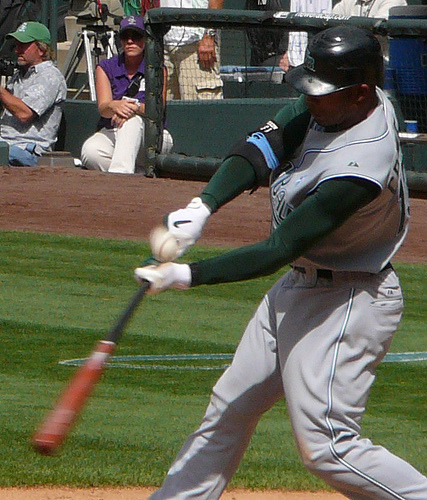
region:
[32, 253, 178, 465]
the baseball bat has two colors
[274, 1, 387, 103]
the player`s helmet is black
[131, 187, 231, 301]
player is wearing gloves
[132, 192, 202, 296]
the gloves are white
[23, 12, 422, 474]
the man is swinging the bat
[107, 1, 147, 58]
the woman is wearing sunglasses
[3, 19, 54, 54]
the hat is green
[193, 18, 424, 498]
the uniform is grey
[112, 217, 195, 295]
the ball is moving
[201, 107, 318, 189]
the player is wearing an arm brace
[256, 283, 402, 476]
The pair of pants is grey.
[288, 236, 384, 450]
The pair of pants is grey.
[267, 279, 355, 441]
The pair of pants is grey.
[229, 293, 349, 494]
The pair of pants is grey.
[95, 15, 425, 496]
The batter is left-handed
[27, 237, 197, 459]
The bat is black and red.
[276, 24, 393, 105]
The batter's helmet is black.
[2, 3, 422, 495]
The batter is swinging a bat.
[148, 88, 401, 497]
The batter's uniform is grey.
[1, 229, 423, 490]
The grass is green.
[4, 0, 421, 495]
The sport is baseball.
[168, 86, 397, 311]
Player's under shirt is green.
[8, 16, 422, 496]
Photo taken during the day.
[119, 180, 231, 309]
White batting gloves on the player.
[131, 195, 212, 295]
pair of white batting gloves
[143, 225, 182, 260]
baseball in flight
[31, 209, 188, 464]
a bat in mid-swing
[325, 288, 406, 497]
stripe on player's left leg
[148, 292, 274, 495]
player swinging against stiff front leg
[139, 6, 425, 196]
padded railing near baseball field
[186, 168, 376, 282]
left arm of batter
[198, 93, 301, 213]
right arm of batter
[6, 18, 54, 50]
green ball cap with white writing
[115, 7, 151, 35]
a purple ball cap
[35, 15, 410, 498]
a baseball player in the midst of swinging his bat to hit the ball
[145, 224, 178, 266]
the white baseball coming past the player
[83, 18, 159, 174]
a woman in white pants, a purple shirt and purple cap watching the game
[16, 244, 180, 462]
the player's red and black baseball bat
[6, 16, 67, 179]
a man wearing a grew shirt and green cap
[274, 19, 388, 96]
the baseball player's black helmet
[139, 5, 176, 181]
a padded railing to the entrance to the dugout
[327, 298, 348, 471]
a white stripe on the player's pants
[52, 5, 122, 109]
a tripod for a camera set up behind the dugout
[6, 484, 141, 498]
a brown patch of dirt at the home base